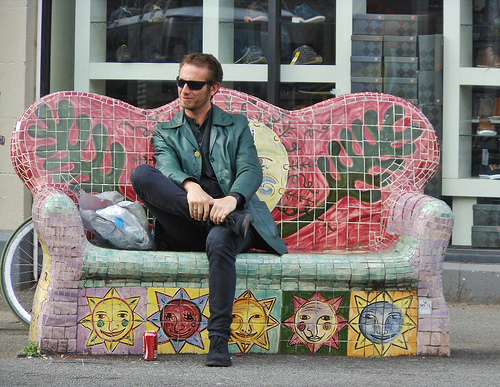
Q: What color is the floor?
A: Gray.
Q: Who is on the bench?
A: A man.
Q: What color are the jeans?
A: Black.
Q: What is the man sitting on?
A: A bench.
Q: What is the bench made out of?
A: Mosaics.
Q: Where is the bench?
A: On a street.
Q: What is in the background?
A: A storefront.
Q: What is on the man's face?
A: Sunglasses.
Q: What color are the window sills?
A: White.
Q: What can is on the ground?
A: Coca-cola.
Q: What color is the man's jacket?
A: Green.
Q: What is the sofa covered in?
A: Tiles.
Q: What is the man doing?
A: Sitting on a bench.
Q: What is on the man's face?
A: Sunglasses.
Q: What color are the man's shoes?
A: Black.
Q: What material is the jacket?
A: Leather.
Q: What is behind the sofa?
A: Bicycle.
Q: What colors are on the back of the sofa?
A: Black, red, and yellow.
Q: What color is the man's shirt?
A: Black.